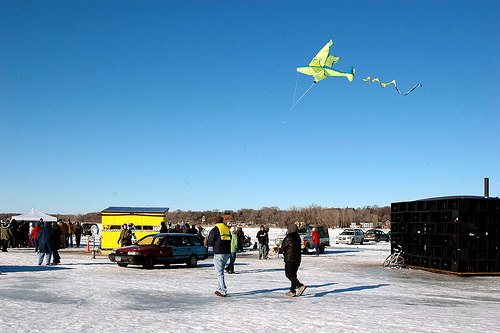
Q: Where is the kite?
A: In the sky.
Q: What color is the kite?
A: Yellow.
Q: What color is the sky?
A: Blue.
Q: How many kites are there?
A: One.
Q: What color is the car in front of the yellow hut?
A: Red and white.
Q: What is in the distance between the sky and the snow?
A: Trees.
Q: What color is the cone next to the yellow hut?
A: Orange.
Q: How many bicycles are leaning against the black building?
A: One.